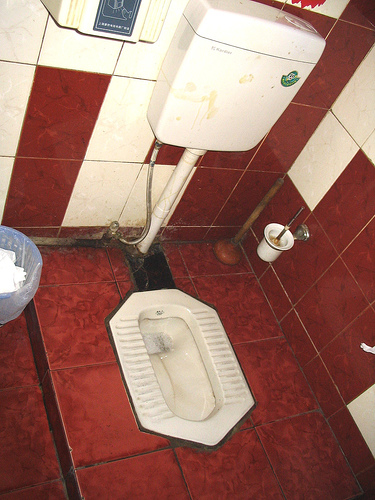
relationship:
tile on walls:
[289, 139, 354, 291] [275, 79, 358, 406]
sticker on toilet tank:
[270, 38, 317, 129] [145, 1, 328, 153]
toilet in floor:
[102, 283, 262, 454] [32, 247, 307, 476]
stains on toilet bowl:
[190, 83, 231, 129] [149, 26, 287, 473]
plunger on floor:
[212, 239, 242, 263] [261, 300, 340, 424]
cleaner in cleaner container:
[267, 226, 286, 246] [255, 221, 295, 264]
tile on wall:
[323, 118, 354, 162] [274, 117, 358, 282]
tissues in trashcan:
[5, 252, 22, 288] [4, 219, 43, 306]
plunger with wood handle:
[212, 239, 242, 263] [227, 184, 284, 231]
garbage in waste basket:
[5, 249, 29, 291] [0, 223, 43, 327]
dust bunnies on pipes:
[115, 222, 131, 233] [102, 207, 198, 269]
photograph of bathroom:
[21, 22, 314, 454] [34, 4, 342, 413]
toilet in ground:
[109, 287, 256, 445] [39, 228, 311, 467]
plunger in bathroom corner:
[204, 223, 263, 281] [209, 133, 328, 274]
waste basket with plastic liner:
[1, 223, 48, 314] [19, 236, 42, 293]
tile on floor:
[35, 354, 113, 446] [0, 236, 363, 499]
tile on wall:
[14, 64, 110, 160] [2, 1, 362, 247]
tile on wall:
[84, 72, 154, 170] [2, 1, 362, 247]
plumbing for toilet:
[107, 143, 209, 256] [103, 1, 330, 453]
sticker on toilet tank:
[281, 71, 300, 87] [145, 1, 328, 154]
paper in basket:
[0, 246, 29, 293] [1, 223, 48, 326]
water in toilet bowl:
[144, 330, 173, 357] [103, 282, 265, 454]